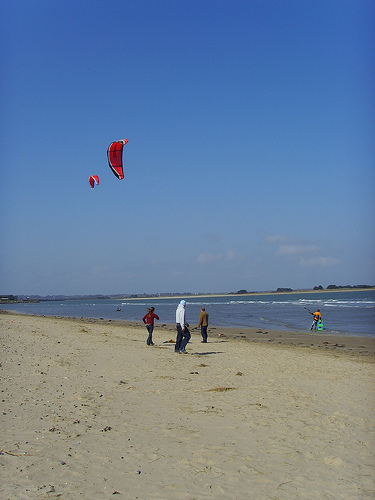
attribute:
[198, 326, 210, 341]
jeans — blue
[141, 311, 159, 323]
shirt — red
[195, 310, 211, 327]
jacket — brown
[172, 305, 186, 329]
shirt — grey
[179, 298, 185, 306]
hoodie — blue 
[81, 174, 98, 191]
kite — red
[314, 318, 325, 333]
treeskiteboard — green 